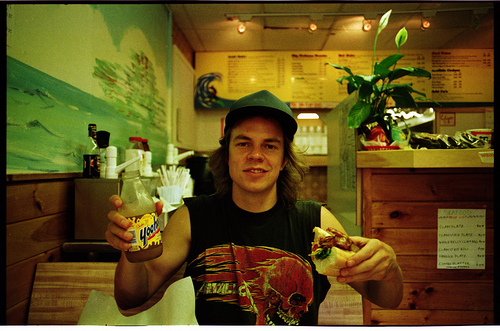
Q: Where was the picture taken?
A: Restaurant.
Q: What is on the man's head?
A: Baseball cap.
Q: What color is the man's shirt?
A: Black.